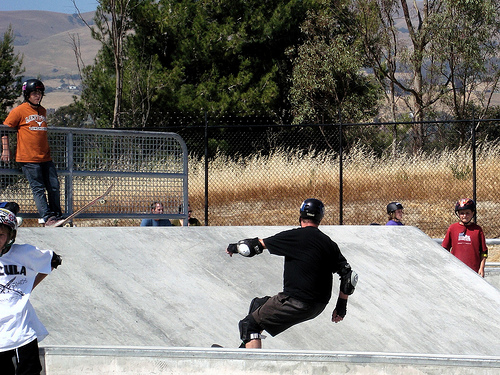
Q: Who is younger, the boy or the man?
A: The boy is younger than the man.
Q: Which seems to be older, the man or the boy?
A: The man is older than the boy.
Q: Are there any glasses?
A: No, there are no glasses.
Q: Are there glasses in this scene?
A: No, there are no glasses.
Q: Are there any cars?
A: No, there are no cars.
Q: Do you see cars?
A: No, there are no cars.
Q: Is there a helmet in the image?
A: Yes, there is a helmet.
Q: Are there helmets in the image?
A: Yes, there is a helmet.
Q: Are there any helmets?
A: Yes, there is a helmet.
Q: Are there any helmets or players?
A: Yes, there is a helmet.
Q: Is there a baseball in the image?
A: No, there are no baseballs.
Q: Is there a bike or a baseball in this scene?
A: No, there are no baseballs or bikes.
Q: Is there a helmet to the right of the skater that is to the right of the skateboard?
A: Yes, there is a helmet to the right of the skater.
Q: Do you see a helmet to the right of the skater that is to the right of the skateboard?
A: Yes, there is a helmet to the right of the skater.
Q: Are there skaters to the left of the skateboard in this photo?
A: Yes, there is a skater to the left of the skateboard.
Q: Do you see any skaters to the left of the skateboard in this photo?
A: Yes, there is a skater to the left of the skateboard.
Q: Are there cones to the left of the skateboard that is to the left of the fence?
A: No, there is a skater to the left of the skateboard.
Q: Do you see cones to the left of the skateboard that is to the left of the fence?
A: No, there is a skater to the left of the skateboard.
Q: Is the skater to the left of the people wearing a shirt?
A: Yes, the skater is wearing a shirt.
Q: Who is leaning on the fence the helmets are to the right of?
A: The skater is leaning on the fence.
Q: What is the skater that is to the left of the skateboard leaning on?
A: The skater is leaning on the fence.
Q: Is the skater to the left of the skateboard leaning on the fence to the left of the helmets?
A: Yes, the skater is leaning on the fence.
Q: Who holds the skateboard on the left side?
A: The skater holds the skateboard.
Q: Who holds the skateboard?
A: The skater holds the skateboard.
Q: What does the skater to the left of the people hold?
A: The skater holds the skateboard.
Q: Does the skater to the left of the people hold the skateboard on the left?
A: Yes, the skater holds the skateboard.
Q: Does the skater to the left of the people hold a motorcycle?
A: No, the skater holds the skateboard.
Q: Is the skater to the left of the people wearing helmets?
A: Yes, the skater is wearing helmets.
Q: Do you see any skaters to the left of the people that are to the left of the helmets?
A: Yes, there is a skater to the left of the people.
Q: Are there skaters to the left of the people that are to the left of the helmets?
A: Yes, there is a skater to the left of the people.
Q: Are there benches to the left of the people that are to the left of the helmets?
A: No, there is a skater to the left of the people.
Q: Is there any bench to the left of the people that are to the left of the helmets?
A: No, there is a skater to the left of the people.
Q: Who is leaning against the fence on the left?
A: The skater is leaning against the fence.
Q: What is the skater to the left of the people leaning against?
A: The skater is leaning against the fence.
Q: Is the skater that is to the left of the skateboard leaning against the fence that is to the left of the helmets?
A: Yes, the skater is leaning against the fence.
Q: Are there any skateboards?
A: Yes, there is a skateboard.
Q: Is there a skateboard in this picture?
A: Yes, there is a skateboard.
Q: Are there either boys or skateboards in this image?
A: Yes, there is a skateboard.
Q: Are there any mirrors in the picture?
A: No, there are no mirrors.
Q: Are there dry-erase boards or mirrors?
A: No, there are no mirrors or dry-erase boards.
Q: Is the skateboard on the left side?
A: Yes, the skateboard is on the left of the image.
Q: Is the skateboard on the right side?
A: No, the skateboard is on the left of the image.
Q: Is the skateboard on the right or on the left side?
A: The skateboard is on the left of the image.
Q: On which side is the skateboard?
A: The skateboard is on the left of the image.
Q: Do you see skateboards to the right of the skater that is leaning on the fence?
A: Yes, there is a skateboard to the right of the skater.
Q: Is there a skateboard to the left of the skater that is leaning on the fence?
A: No, the skateboard is to the right of the skater.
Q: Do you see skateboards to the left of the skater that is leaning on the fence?
A: No, the skateboard is to the right of the skater.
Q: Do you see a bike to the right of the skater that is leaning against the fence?
A: No, there is a skateboard to the right of the skater.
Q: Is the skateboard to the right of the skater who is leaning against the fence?
A: Yes, the skateboard is to the right of the skater.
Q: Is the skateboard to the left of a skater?
A: No, the skateboard is to the right of a skater.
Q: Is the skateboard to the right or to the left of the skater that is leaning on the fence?
A: The skateboard is to the right of the skater.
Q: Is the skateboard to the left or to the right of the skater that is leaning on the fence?
A: The skateboard is to the right of the skater.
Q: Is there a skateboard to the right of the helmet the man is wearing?
A: Yes, there is a skateboard to the right of the helmet.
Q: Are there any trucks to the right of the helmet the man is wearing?
A: No, there is a skateboard to the right of the helmet.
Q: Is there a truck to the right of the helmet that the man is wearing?
A: No, there is a skateboard to the right of the helmet.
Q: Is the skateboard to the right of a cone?
A: No, the skateboard is to the right of the helmet.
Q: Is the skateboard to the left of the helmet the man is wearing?
A: No, the skateboard is to the right of the helmet.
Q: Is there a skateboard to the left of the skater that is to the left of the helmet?
A: Yes, there is a skateboard to the left of the skater.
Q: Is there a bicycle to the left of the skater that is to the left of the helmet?
A: No, there is a skateboard to the left of the skater.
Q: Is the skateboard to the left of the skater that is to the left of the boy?
A: Yes, the skateboard is to the left of the skater.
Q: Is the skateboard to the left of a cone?
A: No, the skateboard is to the left of the skater.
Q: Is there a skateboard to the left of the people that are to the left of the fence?
A: Yes, there is a skateboard to the left of the people.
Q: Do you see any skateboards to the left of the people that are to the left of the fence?
A: Yes, there is a skateboard to the left of the people.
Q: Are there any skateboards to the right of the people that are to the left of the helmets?
A: No, the skateboard is to the left of the people.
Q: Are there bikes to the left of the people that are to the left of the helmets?
A: No, there is a skateboard to the left of the people.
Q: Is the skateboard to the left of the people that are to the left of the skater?
A: Yes, the skateboard is to the left of the people.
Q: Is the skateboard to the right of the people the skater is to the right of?
A: No, the skateboard is to the left of the people.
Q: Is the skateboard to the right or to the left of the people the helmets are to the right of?
A: The skateboard is to the left of the people.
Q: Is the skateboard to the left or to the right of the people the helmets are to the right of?
A: The skateboard is to the left of the people.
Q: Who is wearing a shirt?
A: The skater is wearing a shirt.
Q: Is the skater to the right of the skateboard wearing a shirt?
A: Yes, the skater is wearing a shirt.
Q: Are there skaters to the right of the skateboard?
A: Yes, there is a skater to the right of the skateboard.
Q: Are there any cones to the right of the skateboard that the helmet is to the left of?
A: No, there is a skater to the right of the skateboard.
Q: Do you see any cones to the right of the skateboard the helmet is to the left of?
A: No, there is a skater to the right of the skateboard.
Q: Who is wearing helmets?
A: The skater is wearing helmets.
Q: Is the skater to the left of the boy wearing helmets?
A: Yes, the skater is wearing helmets.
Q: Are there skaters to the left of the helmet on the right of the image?
A: Yes, there is a skater to the left of the helmet.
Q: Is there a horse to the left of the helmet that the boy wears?
A: No, there is a skater to the left of the helmet.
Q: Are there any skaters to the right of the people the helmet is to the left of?
A: Yes, there is a skater to the right of the people.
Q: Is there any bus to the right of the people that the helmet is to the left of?
A: No, there is a skater to the right of the people.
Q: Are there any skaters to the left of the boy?
A: Yes, there is a skater to the left of the boy.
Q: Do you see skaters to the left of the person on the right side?
A: Yes, there is a skater to the left of the boy.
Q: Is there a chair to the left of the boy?
A: No, there is a skater to the left of the boy.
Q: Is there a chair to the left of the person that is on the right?
A: No, there is a skater to the left of the boy.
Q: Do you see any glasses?
A: No, there are no glasses.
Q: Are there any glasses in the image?
A: No, there are no glasses.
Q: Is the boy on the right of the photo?
A: Yes, the boy is on the right of the image.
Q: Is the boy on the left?
A: No, the boy is on the right of the image.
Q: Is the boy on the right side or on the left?
A: The boy is on the right of the image.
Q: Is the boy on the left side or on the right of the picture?
A: The boy is on the right of the image.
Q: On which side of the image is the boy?
A: The boy is on the right of the image.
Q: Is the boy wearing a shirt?
A: Yes, the boy is wearing a shirt.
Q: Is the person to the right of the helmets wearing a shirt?
A: Yes, the boy is wearing a shirt.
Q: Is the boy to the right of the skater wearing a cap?
A: No, the boy is wearing a shirt.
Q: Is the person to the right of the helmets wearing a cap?
A: No, the boy is wearing a shirt.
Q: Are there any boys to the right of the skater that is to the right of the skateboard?
A: Yes, there is a boy to the right of the skater.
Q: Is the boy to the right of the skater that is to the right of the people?
A: Yes, the boy is to the right of the skater.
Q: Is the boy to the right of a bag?
A: No, the boy is to the right of the skater.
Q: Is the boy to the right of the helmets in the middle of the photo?
A: Yes, the boy is to the right of the helmets.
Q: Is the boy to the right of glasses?
A: No, the boy is to the right of the helmets.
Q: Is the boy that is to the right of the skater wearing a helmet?
A: Yes, the boy is wearing a helmet.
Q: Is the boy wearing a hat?
A: No, the boy is wearing a helmet.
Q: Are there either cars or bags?
A: No, there are no cars or bags.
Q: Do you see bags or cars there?
A: No, there are no cars or bags.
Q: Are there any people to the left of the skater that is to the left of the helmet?
A: Yes, there are people to the left of the skater.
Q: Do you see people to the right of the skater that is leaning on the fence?
A: Yes, there are people to the right of the skater.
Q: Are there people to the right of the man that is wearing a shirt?
A: Yes, there are people to the right of the man.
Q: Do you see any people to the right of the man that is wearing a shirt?
A: Yes, there are people to the right of the man.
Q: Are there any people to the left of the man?
A: No, the people are to the right of the man.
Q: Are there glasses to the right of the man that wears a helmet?
A: No, there are people to the right of the man.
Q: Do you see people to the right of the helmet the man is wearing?
A: Yes, there are people to the right of the helmet.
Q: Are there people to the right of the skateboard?
A: Yes, there are people to the right of the skateboard.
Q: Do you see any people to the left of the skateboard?
A: No, the people are to the right of the skateboard.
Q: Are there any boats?
A: No, there are no boats.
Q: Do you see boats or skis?
A: No, there are no boats or skis.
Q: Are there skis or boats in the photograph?
A: No, there are no boats or skis.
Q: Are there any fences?
A: Yes, there is a fence.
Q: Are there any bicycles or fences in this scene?
A: Yes, there is a fence.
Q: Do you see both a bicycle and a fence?
A: No, there is a fence but no bicycles.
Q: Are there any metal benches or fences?
A: Yes, there is a metal fence.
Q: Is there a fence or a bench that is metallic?
A: Yes, the fence is metallic.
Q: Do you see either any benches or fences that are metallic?
A: Yes, the fence is metallic.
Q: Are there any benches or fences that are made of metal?
A: Yes, the fence is made of metal.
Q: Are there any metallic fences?
A: Yes, there is a metal fence.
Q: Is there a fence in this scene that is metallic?
A: Yes, there is a fence that is metallic.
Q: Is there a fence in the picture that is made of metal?
A: Yes, there is a fence that is made of metal.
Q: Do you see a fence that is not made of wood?
A: Yes, there is a fence that is made of metal.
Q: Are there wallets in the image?
A: No, there are no wallets.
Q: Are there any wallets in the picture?
A: No, there are no wallets.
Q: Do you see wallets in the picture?
A: No, there are no wallets.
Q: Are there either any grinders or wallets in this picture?
A: No, there are no wallets or grinders.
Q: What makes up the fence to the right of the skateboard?
A: The fence is made of metal.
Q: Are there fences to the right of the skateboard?
A: Yes, there is a fence to the right of the skateboard.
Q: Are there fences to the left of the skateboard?
A: No, the fence is to the right of the skateboard.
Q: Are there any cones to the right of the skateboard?
A: No, there is a fence to the right of the skateboard.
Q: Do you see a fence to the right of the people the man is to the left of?
A: Yes, there is a fence to the right of the people.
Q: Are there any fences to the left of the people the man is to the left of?
A: No, the fence is to the right of the people.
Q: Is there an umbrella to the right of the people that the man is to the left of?
A: No, there is a fence to the right of the people.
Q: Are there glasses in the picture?
A: No, there are no glasses.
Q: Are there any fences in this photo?
A: Yes, there is a fence.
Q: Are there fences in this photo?
A: Yes, there is a fence.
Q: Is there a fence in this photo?
A: Yes, there is a fence.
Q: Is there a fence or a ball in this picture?
A: Yes, there is a fence.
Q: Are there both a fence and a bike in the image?
A: No, there is a fence but no bikes.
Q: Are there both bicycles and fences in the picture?
A: No, there is a fence but no bikes.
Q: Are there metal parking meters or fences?
A: Yes, there is a metal fence.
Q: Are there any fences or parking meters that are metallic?
A: Yes, the fence is metallic.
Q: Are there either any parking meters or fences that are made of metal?
A: Yes, the fence is made of metal.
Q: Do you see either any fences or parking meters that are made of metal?
A: Yes, the fence is made of metal.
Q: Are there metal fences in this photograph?
A: Yes, there is a metal fence.